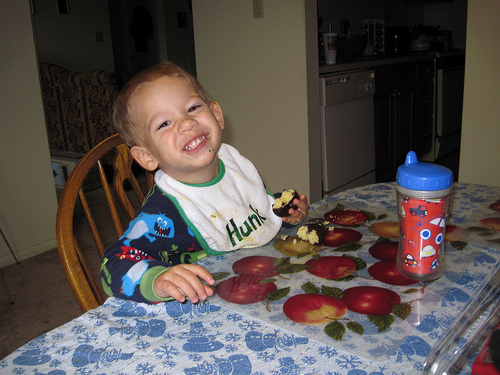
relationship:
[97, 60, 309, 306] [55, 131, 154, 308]
baby in chair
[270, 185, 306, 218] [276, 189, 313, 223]
food in hand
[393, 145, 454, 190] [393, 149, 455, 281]
lid on cup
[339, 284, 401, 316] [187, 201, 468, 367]
apple on place mat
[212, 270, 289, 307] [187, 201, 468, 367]
apple on place mat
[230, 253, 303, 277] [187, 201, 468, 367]
apple on place mat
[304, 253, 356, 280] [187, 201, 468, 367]
apple on place mat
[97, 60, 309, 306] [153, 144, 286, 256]
baby in baby bib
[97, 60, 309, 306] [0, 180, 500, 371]
baby at table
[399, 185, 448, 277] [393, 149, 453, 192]
cup with lid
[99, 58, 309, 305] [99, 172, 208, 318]
baby wearing pajamas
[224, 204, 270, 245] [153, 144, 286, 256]
hunk written across baby bib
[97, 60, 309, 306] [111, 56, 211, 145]
baby has hair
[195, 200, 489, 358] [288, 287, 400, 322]
place mat has apple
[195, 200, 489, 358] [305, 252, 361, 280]
place mat has apple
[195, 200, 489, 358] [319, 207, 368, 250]
place mat has apple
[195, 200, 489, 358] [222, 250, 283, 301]
place mat has apple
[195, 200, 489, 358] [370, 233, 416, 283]
place mat has apple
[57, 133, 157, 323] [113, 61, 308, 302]
chair with boy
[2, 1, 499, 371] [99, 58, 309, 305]
kitchen scene with baby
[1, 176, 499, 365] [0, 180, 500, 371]
cloth on table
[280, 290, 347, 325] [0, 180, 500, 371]
apple on table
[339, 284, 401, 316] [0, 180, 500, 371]
apple on table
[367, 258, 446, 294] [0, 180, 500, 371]
apple on table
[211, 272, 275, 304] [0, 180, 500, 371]
apple on table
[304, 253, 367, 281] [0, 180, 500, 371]
apple on table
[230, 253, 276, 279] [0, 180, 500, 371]
apple on table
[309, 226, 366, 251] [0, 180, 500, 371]
apple on table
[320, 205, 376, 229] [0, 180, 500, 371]
apple on table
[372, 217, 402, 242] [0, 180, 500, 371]
apple on table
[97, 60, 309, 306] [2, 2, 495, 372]
baby smiling at camera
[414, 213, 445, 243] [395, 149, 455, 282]
car on cup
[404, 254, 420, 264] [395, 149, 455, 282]
car on cup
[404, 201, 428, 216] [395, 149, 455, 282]
car on cup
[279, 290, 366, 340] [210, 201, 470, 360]
apple on placemat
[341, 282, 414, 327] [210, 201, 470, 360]
apple on placemat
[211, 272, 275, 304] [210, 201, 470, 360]
apple on placemat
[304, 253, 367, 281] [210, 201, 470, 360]
apple on placemat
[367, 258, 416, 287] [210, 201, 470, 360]
apple on placemat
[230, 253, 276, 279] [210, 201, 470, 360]
apple on placemat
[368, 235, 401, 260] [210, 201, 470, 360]
apple on placemat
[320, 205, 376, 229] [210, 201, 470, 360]
apple on placemat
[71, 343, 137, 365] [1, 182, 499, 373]
snowman on cloth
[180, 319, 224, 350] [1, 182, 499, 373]
snowman on cloth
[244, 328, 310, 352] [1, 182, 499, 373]
snowman on cloth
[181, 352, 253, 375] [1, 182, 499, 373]
snowman on cloth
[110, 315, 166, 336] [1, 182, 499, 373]
snowman on cloth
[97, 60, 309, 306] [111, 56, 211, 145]
baby with hair